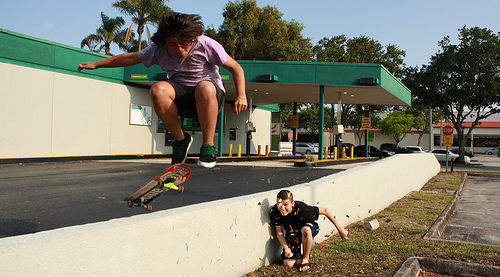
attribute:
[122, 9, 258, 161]
boy — skating, high, visable, tan, jumping, close, younger, young, here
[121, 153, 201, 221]
skateboard — high, red, black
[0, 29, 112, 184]
building — large, white, green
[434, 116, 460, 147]
sign — white, red, small, metal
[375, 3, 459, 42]
sky — blue